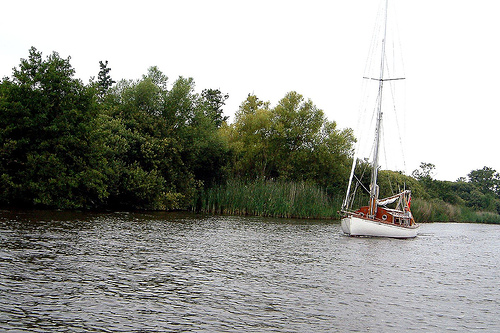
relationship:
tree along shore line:
[30, 63, 85, 216] [2, 196, 498, 223]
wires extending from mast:
[364, 0, 386, 215] [368, 0, 387, 219]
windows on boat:
[356, 211, 390, 224] [338, 31, 419, 238]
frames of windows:
[361, 205, 402, 222] [380, 216, 385, 220]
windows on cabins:
[380, 216, 385, 220] [354, 200, 414, 236]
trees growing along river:
[96, 107, 220, 208] [208, 270, 295, 311]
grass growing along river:
[191, 167, 333, 233] [0, 210, 498, 329]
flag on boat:
[403, 193, 412, 215] [336, 0, 420, 238]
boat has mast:
[336, 0, 420, 238] [349, 0, 412, 204]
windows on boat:
[380, 216, 385, 220] [336, 0, 420, 238]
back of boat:
[390, 187, 423, 244] [325, 2, 453, 231]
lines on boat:
[381, 80, 405, 194] [336, 0, 420, 238]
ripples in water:
[1, 217, 255, 331] [0, 213, 498, 330]